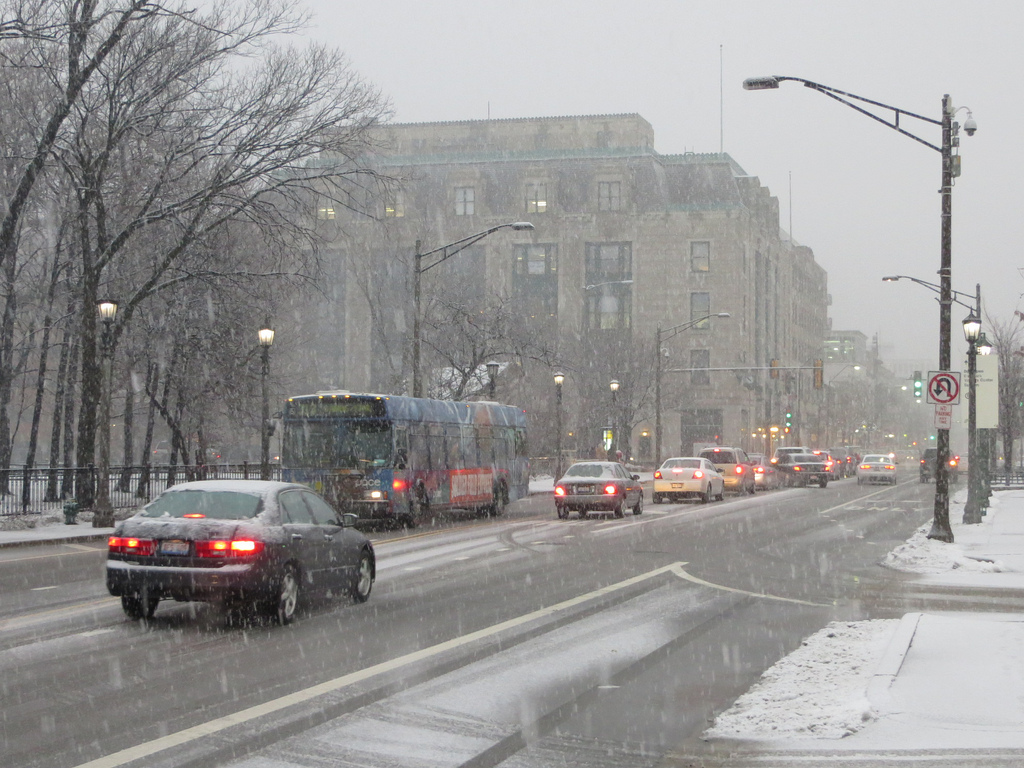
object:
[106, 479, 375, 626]
traffic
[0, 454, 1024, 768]
street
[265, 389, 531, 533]
bus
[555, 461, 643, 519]
traffic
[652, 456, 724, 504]
traffic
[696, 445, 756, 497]
traffic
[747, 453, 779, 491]
traffic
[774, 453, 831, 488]
traffic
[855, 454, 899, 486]
traffic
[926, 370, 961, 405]
sign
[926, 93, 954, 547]
post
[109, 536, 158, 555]
lights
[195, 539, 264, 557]
lights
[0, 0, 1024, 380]
sky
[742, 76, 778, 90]
lamps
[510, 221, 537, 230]
lamps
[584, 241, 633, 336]
windows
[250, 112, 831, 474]
building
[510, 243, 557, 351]
windows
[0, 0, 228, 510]
tree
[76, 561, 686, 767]
line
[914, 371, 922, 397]
light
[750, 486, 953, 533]
lane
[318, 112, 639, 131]
roof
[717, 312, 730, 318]
light